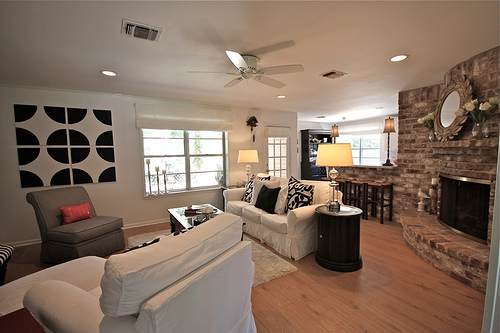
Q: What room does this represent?
A: It represents the living room.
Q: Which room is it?
A: It is a living room.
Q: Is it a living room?
A: Yes, it is a living room.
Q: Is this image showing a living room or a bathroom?
A: It is showing a living room.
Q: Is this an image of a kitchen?
A: No, the picture is showing a living room.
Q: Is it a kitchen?
A: No, it is a living room.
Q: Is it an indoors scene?
A: Yes, it is indoors.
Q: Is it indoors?
A: Yes, it is indoors.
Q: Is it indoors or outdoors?
A: It is indoors.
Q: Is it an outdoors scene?
A: No, it is indoors.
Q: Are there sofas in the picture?
A: Yes, there is a sofa.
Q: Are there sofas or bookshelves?
A: Yes, there is a sofa.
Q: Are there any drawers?
A: No, there are no drawers.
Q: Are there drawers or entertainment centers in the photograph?
A: No, there are no drawers or entertainment centers.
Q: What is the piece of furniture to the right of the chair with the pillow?
A: The piece of furniture is a sofa.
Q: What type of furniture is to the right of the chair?
A: The piece of furniture is a sofa.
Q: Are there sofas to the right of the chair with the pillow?
A: Yes, there is a sofa to the right of the chair.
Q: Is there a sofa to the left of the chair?
A: No, the sofa is to the right of the chair.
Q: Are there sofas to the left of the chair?
A: No, the sofa is to the right of the chair.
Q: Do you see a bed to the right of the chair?
A: No, there is a sofa to the right of the chair.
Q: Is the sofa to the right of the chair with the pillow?
A: Yes, the sofa is to the right of the chair.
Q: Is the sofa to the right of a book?
A: No, the sofa is to the right of the chair.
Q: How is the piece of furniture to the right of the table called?
A: The piece of furniture is a sofa.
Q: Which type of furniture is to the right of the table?
A: The piece of furniture is a sofa.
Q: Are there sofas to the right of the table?
A: Yes, there is a sofa to the right of the table.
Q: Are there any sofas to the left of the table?
A: No, the sofa is to the right of the table.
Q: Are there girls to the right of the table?
A: No, there is a sofa to the right of the table.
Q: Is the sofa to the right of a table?
A: Yes, the sofa is to the right of a table.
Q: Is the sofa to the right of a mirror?
A: No, the sofa is to the right of a table.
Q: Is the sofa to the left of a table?
A: No, the sofa is to the right of a table.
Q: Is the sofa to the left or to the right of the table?
A: The sofa is to the right of the table.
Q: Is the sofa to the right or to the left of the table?
A: The sofa is to the right of the table.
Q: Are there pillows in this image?
A: Yes, there is a pillow.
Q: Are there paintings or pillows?
A: Yes, there is a pillow.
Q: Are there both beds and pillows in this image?
A: No, there is a pillow but no beds.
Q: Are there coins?
A: No, there are no coins.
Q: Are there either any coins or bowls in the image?
A: No, there are no coins or bowls.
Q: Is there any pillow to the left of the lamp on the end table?
A: Yes, there is a pillow to the left of the lamp.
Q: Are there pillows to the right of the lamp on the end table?
A: No, the pillow is to the left of the lamp.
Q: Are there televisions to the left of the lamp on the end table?
A: No, there is a pillow to the left of the lamp.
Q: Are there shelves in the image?
A: No, there are no shelves.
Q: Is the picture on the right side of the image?
A: No, the picture is on the left of the image.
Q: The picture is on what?
A: The picture is on the wall.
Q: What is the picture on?
A: The picture is on the wall.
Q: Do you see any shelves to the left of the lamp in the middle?
A: No, there is a picture to the left of the lamp.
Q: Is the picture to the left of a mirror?
A: No, the picture is to the left of the lamp.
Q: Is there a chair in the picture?
A: Yes, there is a chair.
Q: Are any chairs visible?
A: Yes, there is a chair.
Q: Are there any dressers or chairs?
A: Yes, there is a chair.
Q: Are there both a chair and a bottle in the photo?
A: No, there is a chair but no bottles.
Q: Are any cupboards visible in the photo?
A: No, there are no cupboards.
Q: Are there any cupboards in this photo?
A: No, there are no cupboards.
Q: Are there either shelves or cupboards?
A: No, there are no cupboards or shelves.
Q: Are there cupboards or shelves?
A: No, there are no cupboards or shelves.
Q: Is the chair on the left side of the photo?
A: Yes, the chair is on the left of the image.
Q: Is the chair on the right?
A: No, the chair is on the left of the image.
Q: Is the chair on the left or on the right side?
A: The chair is on the left of the image.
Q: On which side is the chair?
A: The chair is on the left of the image.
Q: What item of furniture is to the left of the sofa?
A: The piece of furniture is a chair.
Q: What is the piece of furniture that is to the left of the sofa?
A: The piece of furniture is a chair.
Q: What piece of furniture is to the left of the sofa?
A: The piece of furniture is a chair.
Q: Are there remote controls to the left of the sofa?
A: No, there is a chair to the left of the sofa.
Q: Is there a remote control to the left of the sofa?
A: No, there is a chair to the left of the sofa.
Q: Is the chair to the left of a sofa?
A: Yes, the chair is to the left of a sofa.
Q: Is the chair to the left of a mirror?
A: No, the chair is to the left of a sofa.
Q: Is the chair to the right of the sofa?
A: No, the chair is to the left of the sofa.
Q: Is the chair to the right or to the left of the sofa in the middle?
A: The chair is to the left of the sofa.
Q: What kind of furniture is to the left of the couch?
A: The piece of furniture is a chair.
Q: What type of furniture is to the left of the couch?
A: The piece of furniture is a chair.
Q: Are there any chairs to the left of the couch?
A: Yes, there is a chair to the left of the couch.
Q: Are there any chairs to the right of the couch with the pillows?
A: No, the chair is to the left of the couch.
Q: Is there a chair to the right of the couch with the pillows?
A: No, the chair is to the left of the couch.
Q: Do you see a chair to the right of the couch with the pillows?
A: No, the chair is to the left of the couch.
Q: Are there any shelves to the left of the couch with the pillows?
A: No, there is a chair to the left of the couch.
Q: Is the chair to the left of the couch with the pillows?
A: Yes, the chair is to the left of the couch.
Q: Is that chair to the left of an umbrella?
A: No, the chair is to the left of the couch.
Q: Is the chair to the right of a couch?
A: No, the chair is to the left of a couch.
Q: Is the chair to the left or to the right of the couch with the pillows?
A: The chair is to the left of the couch.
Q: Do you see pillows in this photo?
A: Yes, there are pillows.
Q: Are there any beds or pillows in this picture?
A: Yes, there are pillows.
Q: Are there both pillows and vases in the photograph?
A: Yes, there are both pillows and a vase.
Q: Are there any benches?
A: No, there are no benches.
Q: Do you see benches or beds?
A: No, there are no benches or beds.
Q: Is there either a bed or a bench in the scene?
A: No, there are no benches or beds.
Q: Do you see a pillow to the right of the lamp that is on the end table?
A: No, the pillows are to the left of the lamp.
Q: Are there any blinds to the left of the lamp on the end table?
A: No, there are pillows to the left of the lamp.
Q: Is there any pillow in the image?
A: Yes, there is a pillow.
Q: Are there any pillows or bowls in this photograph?
A: Yes, there is a pillow.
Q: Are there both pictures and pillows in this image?
A: Yes, there are both a pillow and a picture.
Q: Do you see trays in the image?
A: No, there are no trays.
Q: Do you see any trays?
A: No, there are no trays.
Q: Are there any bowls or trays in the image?
A: No, there are no trays or bowls.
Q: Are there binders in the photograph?
A: No, there are no binders.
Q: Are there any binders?
A: No, there are no binders.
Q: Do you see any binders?
A: No, there are no binders.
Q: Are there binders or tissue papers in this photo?
A: No, there are no binders or tissue papers.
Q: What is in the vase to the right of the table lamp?
A: The roses are in the vase.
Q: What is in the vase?
A: The roses are in the vase.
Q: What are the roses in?
A: The roses are in the vase.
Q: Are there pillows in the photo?
A: Yes, there is a pillow.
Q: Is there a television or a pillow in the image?
A: Yes, there is a pillow.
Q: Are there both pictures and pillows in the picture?
A: Yes, there are both a pillow and a picture.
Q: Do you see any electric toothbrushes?
A: No, there are no electric toothbrushes.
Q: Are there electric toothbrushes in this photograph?
A: No, there are no electric toothbrushes.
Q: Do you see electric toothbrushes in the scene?
A: No, there are no electric toothbrushes.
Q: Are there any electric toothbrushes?
A: No, there are no electric toothbrushes.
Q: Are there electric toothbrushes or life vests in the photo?
A: No, there are no electric toothbrushes or life vests.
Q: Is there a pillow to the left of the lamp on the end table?
A: Yes, there is a pillow to the left of the lamp.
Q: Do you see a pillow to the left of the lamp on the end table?
A: Yes, there is a pillow to the left of the lamp.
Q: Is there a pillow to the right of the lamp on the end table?
A: No, the pillow is to the left of the lamp.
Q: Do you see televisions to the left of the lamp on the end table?
A: No, there is a pillow to the left of the lamp.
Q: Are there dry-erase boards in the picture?
A: No, there are no dry-erase boards.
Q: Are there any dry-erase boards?
A: No, there are no dry-erase boards.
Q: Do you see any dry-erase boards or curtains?
A: No, there are no dry-erase boards or curtains.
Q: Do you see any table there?
A: Yes, there is a table.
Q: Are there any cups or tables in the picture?
A: Yes, there is a table.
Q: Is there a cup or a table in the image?
A: Yes, there is a table.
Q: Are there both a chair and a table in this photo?
A: Yes, there are both a table and a chair.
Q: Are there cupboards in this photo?
A: No, there are no cupboards.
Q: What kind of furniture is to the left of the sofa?
A: The piece of furniture is a table.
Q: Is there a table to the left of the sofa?
A: Yes, there is a table to the left of the sofa.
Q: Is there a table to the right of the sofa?
A: No, the table is to the left of the sofa.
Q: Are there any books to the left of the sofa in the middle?
A: No, there is a table to the left of the sofa.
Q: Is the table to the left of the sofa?
A: Yes, the table is to the left of the sofa.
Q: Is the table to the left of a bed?
A: No, the table is to the left of the sofa.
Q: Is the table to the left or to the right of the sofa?
A: The table is to the left of the sofa.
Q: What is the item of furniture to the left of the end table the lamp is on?
A: The piece of furniture is a table.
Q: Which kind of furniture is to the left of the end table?
A: The piece of furniture is a table.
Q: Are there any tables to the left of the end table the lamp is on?
A: Yes, there is a table to the left of the end table.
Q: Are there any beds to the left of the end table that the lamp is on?
A: No, there is a table to the left of the end table.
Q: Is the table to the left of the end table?
A: Yes, the table is to the left of the end table.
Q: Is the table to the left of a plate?
A: No, the table is to the left of the end table.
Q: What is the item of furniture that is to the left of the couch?
A: The piece of furniture is a table.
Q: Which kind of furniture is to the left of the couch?
A: The piece of furniture is a table.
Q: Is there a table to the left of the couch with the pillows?
A: Yes, there is a table to the left of the couch.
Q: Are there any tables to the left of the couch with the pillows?
A: Yes, there is a table to the left of the couch.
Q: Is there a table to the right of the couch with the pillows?
A: No, the table is to the left of the couch.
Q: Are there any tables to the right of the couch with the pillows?
A: No, the table is to the left of the couch.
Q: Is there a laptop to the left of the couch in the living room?
A: No, there is a table to the left of the couch.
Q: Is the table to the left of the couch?
A: Yes, the table is to the left of the couch.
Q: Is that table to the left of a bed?
A: No, the table is to the left of the couch.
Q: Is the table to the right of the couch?
A: No, the table is to the left of the couch.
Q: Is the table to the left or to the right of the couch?
A: The table is to the left of the couch.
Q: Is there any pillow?
A: Yes, there are pillows.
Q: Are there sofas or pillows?
A: Yes, there are pillows.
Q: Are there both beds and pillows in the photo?
A: No, there are pillows but no beds.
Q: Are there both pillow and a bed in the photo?
A: No, there are pillows but no beds.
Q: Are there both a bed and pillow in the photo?
A: No, there are pillows but no beds.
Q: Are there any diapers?
A: No, there are no diapers.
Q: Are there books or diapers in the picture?
A: No, there are no diapers or books.